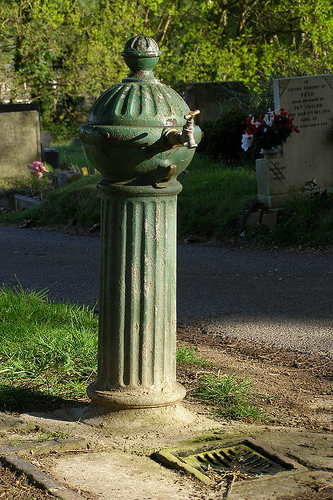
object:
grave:
[256, 72, 332, 233]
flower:
[241, 133, 253, 151]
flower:
[268, 111, 273, 116]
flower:
[251, 124, 254, 130]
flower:
[294, 126, 301, 135]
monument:
[81, 37, 204, 430]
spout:
[165, 108, 201, 150]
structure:
[120, 33, 162, 74]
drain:
[160, 437, 292, 486]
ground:
[2, 126, 331, 495]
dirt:
[133, 418, 301, 450]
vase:
[260, 146, 278, 158]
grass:
[0, 285, 194, 373]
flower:
[28, 161, 48, 179]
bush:
[202, 105, 256, 167]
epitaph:
[284, 79, 330, 134]